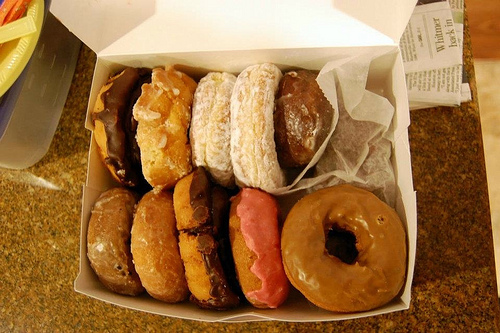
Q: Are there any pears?
A: No, there are no pears.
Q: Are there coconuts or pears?
A: No, there are no pears or coconuts.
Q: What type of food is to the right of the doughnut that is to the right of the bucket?
A: The food is a nut.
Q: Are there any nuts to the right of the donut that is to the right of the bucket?
A: Yes, there is a nut to the right of the doughnut.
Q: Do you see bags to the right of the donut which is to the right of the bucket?
A: No, there is a nut to the right of the doughnut.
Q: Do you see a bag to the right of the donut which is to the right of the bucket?
A: No, there is a nut to the right of the doughnut.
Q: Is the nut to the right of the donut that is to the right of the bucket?
A: Yes, the nut is to the right of the doughnut.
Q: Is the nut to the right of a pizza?
A: No, the nut is to the right of the doughnut.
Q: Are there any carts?
A: No, there are no carts.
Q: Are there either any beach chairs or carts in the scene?
A: No, there are no carts or beach chairs.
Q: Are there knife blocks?
A: No, there are no knife blocks.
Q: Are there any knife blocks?
A: No, there are no knife blocks.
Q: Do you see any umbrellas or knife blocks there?
A: No, there are no knife blocks or umbrellas.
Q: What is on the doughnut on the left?
A: The frosting is on the doughnut.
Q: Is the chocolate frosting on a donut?
A: Yes, the frosting is on a donut.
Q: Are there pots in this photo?
A: No, there are no pots.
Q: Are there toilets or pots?
A: No, there are no pots or toilets.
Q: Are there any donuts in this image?
A: Yes, there is a donut.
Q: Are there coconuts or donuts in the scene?
A: Yes, there is a donut.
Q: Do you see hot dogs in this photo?
A: No, there are no hot dogs.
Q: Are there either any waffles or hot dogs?
A: No, there are no hot dogs or waffles.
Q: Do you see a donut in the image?
A: Yes, there is a donut.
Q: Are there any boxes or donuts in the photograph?
A: Yes, there is a donut.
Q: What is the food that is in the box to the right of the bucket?
A: The food is a donut.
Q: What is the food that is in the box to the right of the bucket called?
A: The food is a donut.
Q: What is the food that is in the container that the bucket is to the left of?
A: The food is a donut.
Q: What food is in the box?
A: The food is a donut.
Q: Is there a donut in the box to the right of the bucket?
A: Yes, there is a donut in the box.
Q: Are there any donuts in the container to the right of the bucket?
A: Yes, there is a donut in the box.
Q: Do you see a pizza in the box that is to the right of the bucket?
A: No, there is a donut in the box.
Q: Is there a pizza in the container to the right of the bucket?
A: No, there is a donut in the box.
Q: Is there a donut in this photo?
A: Yes, there is a donut.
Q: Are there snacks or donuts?
A: Yes, there is a donut.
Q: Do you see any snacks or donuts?
A: Yes, there is a donut.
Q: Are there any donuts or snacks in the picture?
A: Yes, there is a donut.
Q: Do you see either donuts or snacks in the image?
A: Yes, there is a donut.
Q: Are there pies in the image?
A: No, there are no pies.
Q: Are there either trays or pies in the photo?
A: No, there are no pies or trays.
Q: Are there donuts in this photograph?
A: Yes, there is a donut.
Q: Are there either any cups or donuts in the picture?
A: Yes, there is a donut.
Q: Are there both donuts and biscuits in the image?
A: No, there is a donut but no biscuits.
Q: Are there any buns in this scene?
A: No, there are no buns.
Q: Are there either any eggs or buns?
A: No, there are no buns or eggs.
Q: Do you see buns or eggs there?
A: No, there are no buns or eggs.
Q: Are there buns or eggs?
A: No, there are no buns or eggs.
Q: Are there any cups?
A: No, there are no cups.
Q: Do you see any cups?
A: No, there are no cups.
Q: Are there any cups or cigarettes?
A: No, there are no cups or cigarettes.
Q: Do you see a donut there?
A: Yes, there are donuts.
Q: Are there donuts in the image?
A: Yes, there are donuts.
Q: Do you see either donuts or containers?
A: Yes, there are donuts.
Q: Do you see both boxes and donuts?
A: Yes, there are both donuts and a box.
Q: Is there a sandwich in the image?
A: No, there are no sandwiches.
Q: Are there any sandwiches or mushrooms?
A: No, there are no sandwiches or mushrooms.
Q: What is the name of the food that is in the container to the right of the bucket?
A: The food is donuts.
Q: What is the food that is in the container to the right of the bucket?
A: The food is donuts.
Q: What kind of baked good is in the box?
A: The food is donuts.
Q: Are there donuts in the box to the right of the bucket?
A: Yes, there are donuts in the box.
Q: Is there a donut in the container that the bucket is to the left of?
A: Yes, there are donuts in the box.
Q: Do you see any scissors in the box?
A: No, there are donuts in the box.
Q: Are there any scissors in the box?
A: No, there are donuts in the box.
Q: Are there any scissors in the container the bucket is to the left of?
A: No, there are donuts in the box.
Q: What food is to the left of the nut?
A: The food is donuts.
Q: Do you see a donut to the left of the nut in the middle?
A: Yes, there are donuts to the left of the nut.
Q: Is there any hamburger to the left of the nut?
A: No, there are donuts to the left of the nut.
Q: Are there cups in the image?
A: No, there are no cups.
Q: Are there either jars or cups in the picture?
A: No, there are no cups or jars.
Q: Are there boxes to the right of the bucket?
A: Yes, there is a box to the right of the bucket.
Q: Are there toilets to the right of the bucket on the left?
A: No, there is a box to the right of the bucket.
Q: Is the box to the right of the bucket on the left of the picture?
A: Yes, the box is to the right of the bucket.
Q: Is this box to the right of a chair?
A: No, the box is to the right of the bucket.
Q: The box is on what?
A: The box is on the doughnut.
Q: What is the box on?
A: The box is on the doughnut.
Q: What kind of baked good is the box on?
A: The box is on the doughnut.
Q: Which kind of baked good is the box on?
A: The box is on the doughnut.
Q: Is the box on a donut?
A: Yes, the box is on a donut.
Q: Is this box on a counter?
A: No, the box is on a donut.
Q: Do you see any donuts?
A: Yes, there is a donut.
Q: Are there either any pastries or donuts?
A: Yes, there is a donut.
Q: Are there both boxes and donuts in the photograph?
A: Yes, there are both a donut and a box.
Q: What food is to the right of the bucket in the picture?
A: The food is a donut.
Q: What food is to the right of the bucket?
A: The food is a donut.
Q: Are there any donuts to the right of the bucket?
A: Yes, there is a donut to the right of the bucket.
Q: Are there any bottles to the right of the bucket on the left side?
A: No, there is a donut to the right of the bucket.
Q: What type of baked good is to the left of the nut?
A: The food is a donut.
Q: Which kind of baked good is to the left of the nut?
A: The food is a donut.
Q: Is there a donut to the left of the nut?
A: Yes, there is a donut to the left of the nut.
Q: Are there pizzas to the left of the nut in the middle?
A: No, there is a donut to the left of the nut.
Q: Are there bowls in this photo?
A: No, there are no bowls.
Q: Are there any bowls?
A: No, there are no bowls.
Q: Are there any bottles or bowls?
A: No, there are no bowls or bottles.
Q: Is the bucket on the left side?
A: Yes, the bucket is on the left of the image.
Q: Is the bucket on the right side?
A: No, the bucket is on the left of the image.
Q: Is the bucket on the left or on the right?
A: The bucket is on the left of the image.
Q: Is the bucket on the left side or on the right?
A: The bucket is on the left of the image.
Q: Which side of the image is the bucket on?
A: The bucket is on the left of the image.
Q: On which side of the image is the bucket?
A: The bucket is on the left of the image.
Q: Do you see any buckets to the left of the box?
A: Yes, there is a bucket to the left of the box.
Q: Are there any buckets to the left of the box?
A: Yes, there is a bucket to the left of the box.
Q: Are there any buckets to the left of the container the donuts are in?
A: Yes, there is a bucket to the left of the box.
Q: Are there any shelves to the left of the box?
A: No, there is a bucket to the left of the box.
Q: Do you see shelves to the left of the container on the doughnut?
A: No, there is a bucket to the left of the box.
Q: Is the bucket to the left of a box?
A: Yes, the bucket is to the left of a box.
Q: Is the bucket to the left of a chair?
A: No, the bucket is to the left of a box.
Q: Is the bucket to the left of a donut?
A: Yes, the bucket is to the left of a donut.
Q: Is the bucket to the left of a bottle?
A: No, the bucket is to the left of a donut.